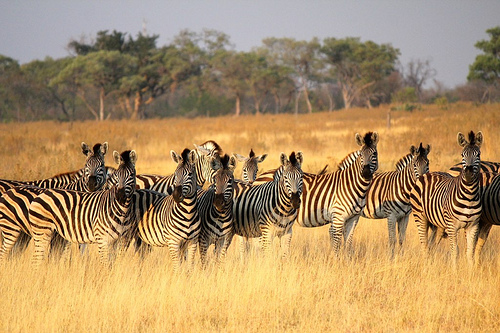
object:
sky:
[0, 1, 500, 92]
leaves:
[323, 36, 402, 111]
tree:
[47, 28, 142, 124]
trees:
[257, 35, 323, 116]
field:
[0, 101, 500, 332]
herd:
[0, 130, 500, 274]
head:
[354, 130, 380, 180]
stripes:
[289, 147, 369, 248]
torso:
[293, 158, 342, 226]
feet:
[446, 228, 459, 280]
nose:
[360, 164, 373, 180]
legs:
[328, 219, 346, 253]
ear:
[355, 134, 362, 147]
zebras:
[0, 141, 109, 262]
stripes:
[38, 196, 84, 228]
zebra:
[410, 131, 485, 274]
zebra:
[358, 141, 429, 252]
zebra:
[254, 130, 382, 256]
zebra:
[218, 150, 305, 262]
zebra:
[232, 148, 268, 184]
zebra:
[194, 154, 236, 269]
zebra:
[133, 147, 199, 270]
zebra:
[27, 149, 138, 277]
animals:
[410, 130, 485, 278]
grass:
[169, 285, 252, 308]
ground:
[200, 255, 288, 286]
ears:
[457, 131, 468, 147]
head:
[457, 130, 485, 181]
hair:
[289, 151, 298, 165]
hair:
[337, 150, 362, 171]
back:
[301, 170, 340, 190]